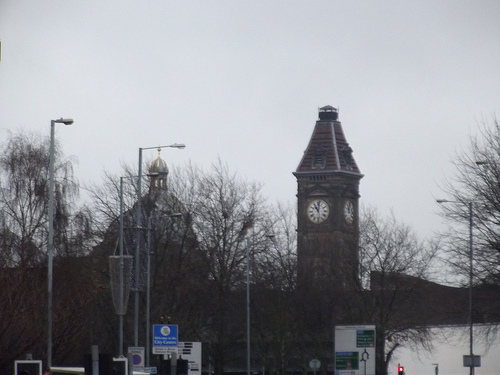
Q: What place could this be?
A: It is a city.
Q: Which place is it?
A: It is a city.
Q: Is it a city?
A: Yes, it is a city.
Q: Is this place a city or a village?
A: It is a city.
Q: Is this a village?
A: No, it is a city.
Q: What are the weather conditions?
A: It is overcast.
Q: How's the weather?
A: It is overcast.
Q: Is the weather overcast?
A: Yes, it is overcast.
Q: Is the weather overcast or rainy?
A: It is overcast.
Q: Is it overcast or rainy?
A: It is overcast.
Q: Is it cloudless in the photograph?
A: No, it is overcast.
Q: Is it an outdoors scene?
A: Yes, it is outdoors.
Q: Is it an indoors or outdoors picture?
A: It is outdoors.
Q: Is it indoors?
A: No, it is outdoors.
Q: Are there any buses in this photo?
A: No, there are no buses.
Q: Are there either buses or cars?
A: No, there are no buses or cars.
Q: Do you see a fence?
A: No, there are no fences.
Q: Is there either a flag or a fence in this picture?
A: No, there are no fences or flags.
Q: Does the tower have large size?
A: Yes, the tower is large.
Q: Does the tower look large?
A: Yes, the tower is large.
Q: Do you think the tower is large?
A: Yes, the tower is large.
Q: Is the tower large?
A: Yes, the tower is large.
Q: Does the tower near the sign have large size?
A: Yes, the tower is large.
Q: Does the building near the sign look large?
A: Yes, the tower is large.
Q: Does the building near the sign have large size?
A: Yes, the tower is large.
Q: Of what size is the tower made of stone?
A: The tower is large.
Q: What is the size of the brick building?
A: The tower is large.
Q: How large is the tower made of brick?
A: The tower is large.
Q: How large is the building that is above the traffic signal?
A: The tower is large.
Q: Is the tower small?
A: No, the tower is large.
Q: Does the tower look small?
A: No, the tower is large.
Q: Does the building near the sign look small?
A: No, the tower is large.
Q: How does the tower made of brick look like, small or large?
A: The tower is large.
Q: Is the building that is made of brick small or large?
A: The tower is large.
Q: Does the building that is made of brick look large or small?
A: The tower is large.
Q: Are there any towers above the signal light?
A: Yes, there is a tower above the signal light.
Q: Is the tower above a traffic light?
A: Yes, the tower is above a traffic light.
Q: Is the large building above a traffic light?
A: Yes, the tower is above a traffic light.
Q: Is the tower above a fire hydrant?
A: No, the tower is above a traffic light.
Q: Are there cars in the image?
A: No, there are no cars.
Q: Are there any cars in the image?
A: No, there are no cars.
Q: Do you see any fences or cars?
A: No, there are no cars or fences.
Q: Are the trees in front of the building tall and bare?
A: Yes, the trees are tall and bare.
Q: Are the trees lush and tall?
A: No, the trees are tall but bare.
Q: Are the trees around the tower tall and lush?
A: No, the trees are tall but bare.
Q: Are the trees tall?
A: Yes, the trees are tall.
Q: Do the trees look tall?
A: Yes, the trees are tall.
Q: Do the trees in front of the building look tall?
A: Yes, the trees are tall.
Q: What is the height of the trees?
A: The trees are tall.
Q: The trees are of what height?
A: The trees are tall.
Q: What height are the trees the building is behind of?
A: The trees are tall.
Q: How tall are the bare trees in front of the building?
A: The trees are tall.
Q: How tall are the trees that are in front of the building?
A: The trees are tall.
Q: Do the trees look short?
A: No, the trees are tall.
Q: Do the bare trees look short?
A: No, the trees are tall.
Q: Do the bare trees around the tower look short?
A: No, the trees are tall.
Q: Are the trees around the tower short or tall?
A: The trees are tall.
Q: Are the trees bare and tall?
A: Yes, the trees are bare and tall.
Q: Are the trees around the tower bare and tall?
A: Yes, the trees are bare and tall.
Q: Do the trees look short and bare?
A: No, the trees are bare but tall.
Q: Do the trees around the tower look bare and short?
A: No, the trees are bare but tall.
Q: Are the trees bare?
A: Yes, the trees are bare.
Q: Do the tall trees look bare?
A: Yes, the trees are bare.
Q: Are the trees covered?
A: No, the trees are bare.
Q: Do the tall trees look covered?
A: No, the trees are bare.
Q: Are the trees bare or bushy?
A: The trees are bare.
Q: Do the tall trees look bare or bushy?
A: The trees are bare.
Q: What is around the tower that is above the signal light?
A: The trees are around the tower.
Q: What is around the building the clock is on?
A: The trees are around the tower.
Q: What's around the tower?
A: The trees are around the tower.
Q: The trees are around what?
A: The trees are around the tower.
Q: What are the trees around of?
A: The trees are around the tower.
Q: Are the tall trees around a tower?
A: Yes, the trees are around a tower.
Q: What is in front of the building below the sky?
A: The trees are in front of the building.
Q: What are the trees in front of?
A: The trees are in front of the building.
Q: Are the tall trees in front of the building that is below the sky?
A: Yes, the trees are in front of the building.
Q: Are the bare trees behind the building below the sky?
A: No, the trees are in front of the building.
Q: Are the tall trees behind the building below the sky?
A: No, the trees are in front of the building.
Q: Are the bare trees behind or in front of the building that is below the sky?
A: The trees are in front of the building.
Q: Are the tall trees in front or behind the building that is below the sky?
A: The trees are in front of the building.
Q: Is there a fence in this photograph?
A: No, there are no fences.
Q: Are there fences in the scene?
A: No, there are no fences.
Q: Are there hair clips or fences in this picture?
A: No, there are no fences or hair clips.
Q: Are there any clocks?
A: Yes, there is a clock.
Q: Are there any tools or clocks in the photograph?
A: Yes, there is a clock.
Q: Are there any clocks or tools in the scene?
A: Yes, there is a clock.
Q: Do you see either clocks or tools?
A: Yes, there is a clock.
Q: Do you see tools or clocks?
A: Yes, there is a clock.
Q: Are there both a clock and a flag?
A: No, there is a clock but no flags.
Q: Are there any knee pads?
A: No, there are no knee pads.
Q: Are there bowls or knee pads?
A: No, there are no knee pads or bowls.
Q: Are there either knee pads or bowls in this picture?
A: No, there are no knee pads or bowls.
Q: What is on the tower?
A: The clock is on the tower.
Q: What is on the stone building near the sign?
A: The clock is on the tower.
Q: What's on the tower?
A: The clock is on the tower.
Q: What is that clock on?
A: The clock is on the tower.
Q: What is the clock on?
A: The clock is on the tower.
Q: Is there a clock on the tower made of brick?
A: Yes, there is a clock on the tower.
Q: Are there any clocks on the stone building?
A: Yes, there is a clock on the tower.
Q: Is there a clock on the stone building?
A: Yes, there is a clock on the tower.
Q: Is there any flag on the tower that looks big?
A: No, there is a clock on the tower.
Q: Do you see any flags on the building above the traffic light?
A: No, there is a clock on the tower.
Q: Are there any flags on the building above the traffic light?
A: No, there is a clock on the tower.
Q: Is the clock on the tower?
A: Yes, the clock is on the tower.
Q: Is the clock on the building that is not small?
A: Yes, the clock is on the tower.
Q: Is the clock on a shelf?
A: No, the clock is on the tower.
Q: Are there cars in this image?
A: No, there are no cars.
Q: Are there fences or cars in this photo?
A: No, there are no cars or fences.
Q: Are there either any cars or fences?
A: No, there are no cars or fences.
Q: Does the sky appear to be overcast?
A: Yes, the sky is overcast.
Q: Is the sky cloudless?
A: No, the sky is overcast.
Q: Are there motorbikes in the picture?
A: No, there are no motorbikes.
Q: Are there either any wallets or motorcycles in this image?
A: No, there are no motorcycles or wallets.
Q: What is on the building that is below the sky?
A: The dome is on the building.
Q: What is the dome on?
A: The dome is on the building.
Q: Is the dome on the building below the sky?
A: Yes, the dome is on the building.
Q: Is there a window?
A: Yes, there is a window.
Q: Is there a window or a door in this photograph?
A: Yes, there is a window.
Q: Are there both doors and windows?
A: No, there is a window but no doors.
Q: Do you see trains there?
A: No, there are no trains.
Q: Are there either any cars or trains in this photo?
A: No, there are no trains or cars.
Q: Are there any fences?
A: No, there are no fences.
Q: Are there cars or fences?
A: No, there are no fences or cars.